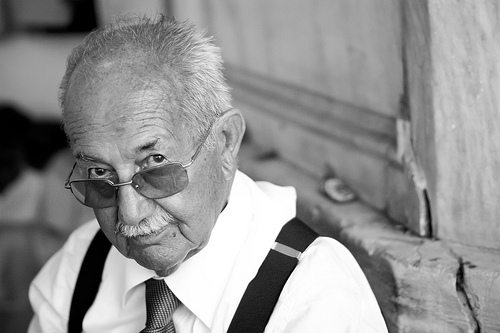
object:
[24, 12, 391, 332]
man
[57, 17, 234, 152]
hair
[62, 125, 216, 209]
glasses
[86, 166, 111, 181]
eye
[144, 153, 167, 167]
eye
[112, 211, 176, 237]
moustache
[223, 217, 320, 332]
suspender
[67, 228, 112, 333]
suspender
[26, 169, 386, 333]
shirt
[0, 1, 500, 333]
photo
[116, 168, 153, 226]
nose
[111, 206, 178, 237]
mustache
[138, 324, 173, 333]
knot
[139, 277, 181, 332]
necktie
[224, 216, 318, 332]
strap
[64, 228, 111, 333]
strap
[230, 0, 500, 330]
wall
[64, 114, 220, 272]
face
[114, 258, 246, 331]
collar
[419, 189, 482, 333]
crack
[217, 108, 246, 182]
ear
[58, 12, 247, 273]
head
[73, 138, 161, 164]
eyebrow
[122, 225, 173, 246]
mouth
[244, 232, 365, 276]
shoulder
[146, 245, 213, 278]
neck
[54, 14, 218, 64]
top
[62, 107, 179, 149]
creases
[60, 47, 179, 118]
forhead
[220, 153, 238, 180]
lobe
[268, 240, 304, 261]
metal